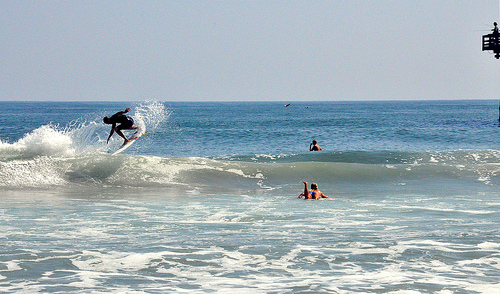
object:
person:
[297, 180, 334, 200]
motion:
[100, 106, 153, 156]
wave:
[0, 100, 499, 200]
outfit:
[108, 112, 134, 130]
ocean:
[0, 100, 499, 294]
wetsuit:
[109, 112, 134, 133]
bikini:
[309, 190, 315, 195]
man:
[103, 107, 141, 144]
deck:
[480, 23, 499, 60]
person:
[489, 21, 500, 33]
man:
[309, 139, 322, 152]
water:
[0, 100, 499, 293]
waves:
[0, 189, 499, 293]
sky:
[0, 0, 497, 102]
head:
[102, 116, 110, 124]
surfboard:
[110, 127, 145, 156]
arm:
[113, 111, 124, 117]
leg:
[114, 125, 125, 138]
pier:
[479, 34, 499, 59]